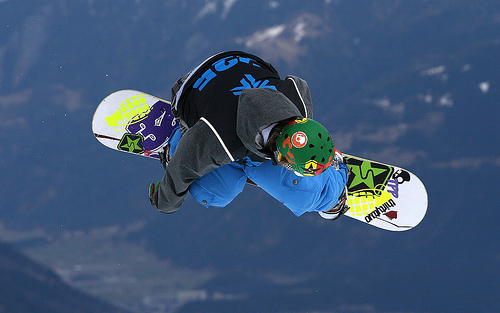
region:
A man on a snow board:
[92, 50, 428, 232]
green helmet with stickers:
[277, 114, 333, 176]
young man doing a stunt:
[89, 48, 429, 232]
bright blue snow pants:
[164, 120, 346, 224]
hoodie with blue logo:
[149, 51, 311, 216]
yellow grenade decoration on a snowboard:
[105, 90, 151, 128]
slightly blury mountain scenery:
[1, 1, 498, 311]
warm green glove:
[146, 171, 187, 214]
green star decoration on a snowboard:
[344, 156, 394, 196]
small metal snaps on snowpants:
[193, 168, 312, 215]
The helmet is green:
[272, 115, 332, 178]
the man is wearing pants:
[174, 44, 368, 236]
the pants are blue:
[169, 119, 372, 230]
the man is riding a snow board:
[84, 16, 464, 269]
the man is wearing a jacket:
[148, 47, 358, 245]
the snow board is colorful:
[95, 101, 425, 229]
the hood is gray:
[228, 77, 290, 153]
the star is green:
[347, 158, 394, 192]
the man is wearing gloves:
[131, 168, 213, 240]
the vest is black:
[175, 66, 313, 154]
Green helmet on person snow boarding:
[272, 109, 335, 177]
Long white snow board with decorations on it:
[85, 89, 429, 229]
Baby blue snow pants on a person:
[168, 125, 348, 216]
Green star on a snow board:
[346, 158, 387, 196]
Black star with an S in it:
[301, 161, 319, 177]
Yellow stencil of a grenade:
[104, 97, 151, 129]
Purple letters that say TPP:
[385, 178, 400, 200]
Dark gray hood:
[239, 89, 297, 156]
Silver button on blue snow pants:
[287, 177, 297, 187]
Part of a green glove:
[145, 182, 161, 207]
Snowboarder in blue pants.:
[38, 13, 450, 249]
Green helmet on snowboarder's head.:
[253, 113, 350, 185]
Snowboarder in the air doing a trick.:
[146, 27, 349, 262]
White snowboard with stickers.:
[81, 86, 432, 236]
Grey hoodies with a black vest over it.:
[136, 19, 314, 217]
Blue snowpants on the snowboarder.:
[158, 121, 353, 225]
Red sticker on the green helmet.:
[288, 125, 310, 155]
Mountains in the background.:
[14, 13, 484, 300]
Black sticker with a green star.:
[339, 151, 396, 200]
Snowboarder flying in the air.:
[57, 36, 451, 243]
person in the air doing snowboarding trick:
[46, 36, 455, 251]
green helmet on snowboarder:
[241, 110, 353, 187]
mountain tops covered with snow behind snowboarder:
[354, 12, 491, 143]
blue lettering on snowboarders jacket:
[192, 45, 274, 97]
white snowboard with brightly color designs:
[345, 151, 444, 223]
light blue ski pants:
[257, 178, 347, 224]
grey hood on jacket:
[220, 75, 331, 165]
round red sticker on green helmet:
[285, 125, 317, 150]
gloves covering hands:
[132, 172, 201, 224]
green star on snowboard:
[335, 139, 394, 198]